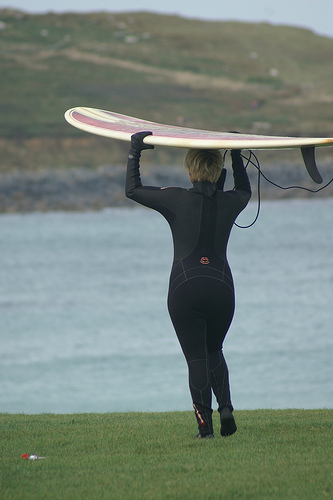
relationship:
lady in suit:
[111, 141, 293, 469] [136, 177, 274, 313]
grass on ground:
[122, 422, 151, 432] [114, 382, 202, 477]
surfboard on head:
[188, 99, 305, 189] [199, 155, 220, 181]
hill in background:
[225, 27, 308, 68] [50, 37, 312, 271]